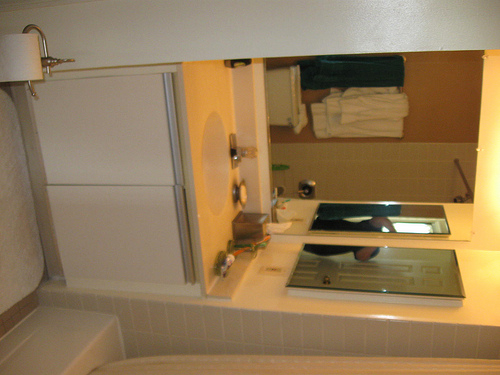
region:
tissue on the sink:
[240, 198, 284, 250]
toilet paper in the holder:
[1, 13, 66, 100]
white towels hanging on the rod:
[328, 83, 403, 143]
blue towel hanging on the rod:
[295, 59, 418, 105]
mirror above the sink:
[265, 62, 485, 207]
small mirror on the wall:
[287, 239, 482, 309]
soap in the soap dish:
[225, 180, 258, 210]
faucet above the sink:
[231, 129, 261, 171]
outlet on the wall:
[252, 252, 292, 281]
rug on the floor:
[0, 98, 49, 320]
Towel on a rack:
[313, 87, 411, 145]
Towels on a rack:
[310, 86, 411, 143]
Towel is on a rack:
[309, 86, 409, 147]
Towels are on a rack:
[307, 86, 411, 146]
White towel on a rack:
[309, 85, 408, 141]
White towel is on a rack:
[305, 86, 412, 145]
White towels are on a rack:
[305, 87, 412, 144]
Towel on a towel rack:
[310, 88, 408, 142]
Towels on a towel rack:
[304, 89, 408, 143]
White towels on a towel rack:
[305, 85, 412, 146]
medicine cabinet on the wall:
[280, 240, 465, 310]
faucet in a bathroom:
[227, 130, 262, 172]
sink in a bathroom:
[194, 106, 244, 221]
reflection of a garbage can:
[264, 60, 316, 136]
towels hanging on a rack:
[308, 84, 415, 144]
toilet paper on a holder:
[0, 23, 78, 109]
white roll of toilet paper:
[0, 28, 50, 88]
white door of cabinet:
[29, 68, 189, 192]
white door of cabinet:
[37, 180, 195, 300]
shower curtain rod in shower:
[450, 151, 477, 203]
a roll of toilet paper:
[0, 7, 68, 86]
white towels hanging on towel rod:
[317, 69, 406, 136]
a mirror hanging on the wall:
[270, 241, 490, 326]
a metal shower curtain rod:
[447, 145, 472, 205]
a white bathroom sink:
[152, 114, 269, 229]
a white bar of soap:
[227, 181, 256, 201]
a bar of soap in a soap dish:
[222, 173, 256, 207]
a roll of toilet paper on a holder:
[0, 2, 61, 95]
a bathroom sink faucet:
[215, 137, 266, 167]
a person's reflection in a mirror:
[296, 239, 388, 268]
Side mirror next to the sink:
[281, 238, 472, 314]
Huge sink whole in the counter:
[203, 105, 233, 220]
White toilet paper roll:
[0, 20, 67, 100]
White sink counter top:
[181, 62, 252, 294]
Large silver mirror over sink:
[262, 51, 479, 208]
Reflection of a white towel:
[317, 86, 410, 141]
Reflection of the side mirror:
[316, 189, 445, 231]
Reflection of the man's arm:
[294, 237, 382, 262]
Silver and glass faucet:
[226, 130, 256, 176]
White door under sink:
[23, 72, 180, 186]